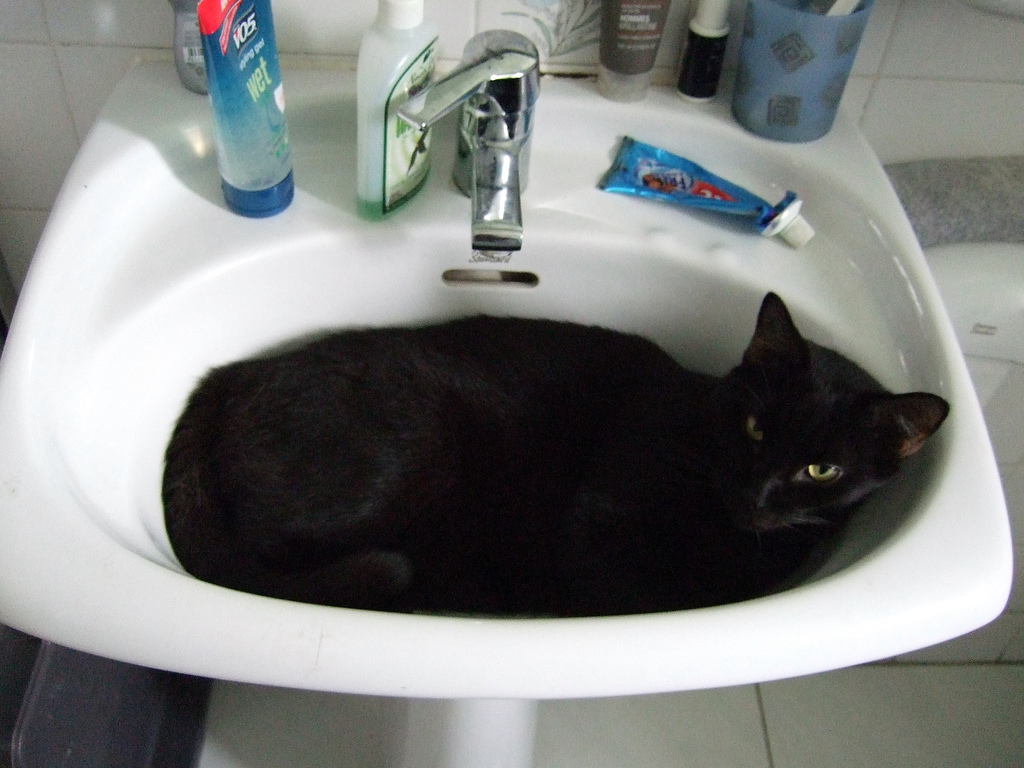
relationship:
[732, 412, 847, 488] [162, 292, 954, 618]
eyes on cat